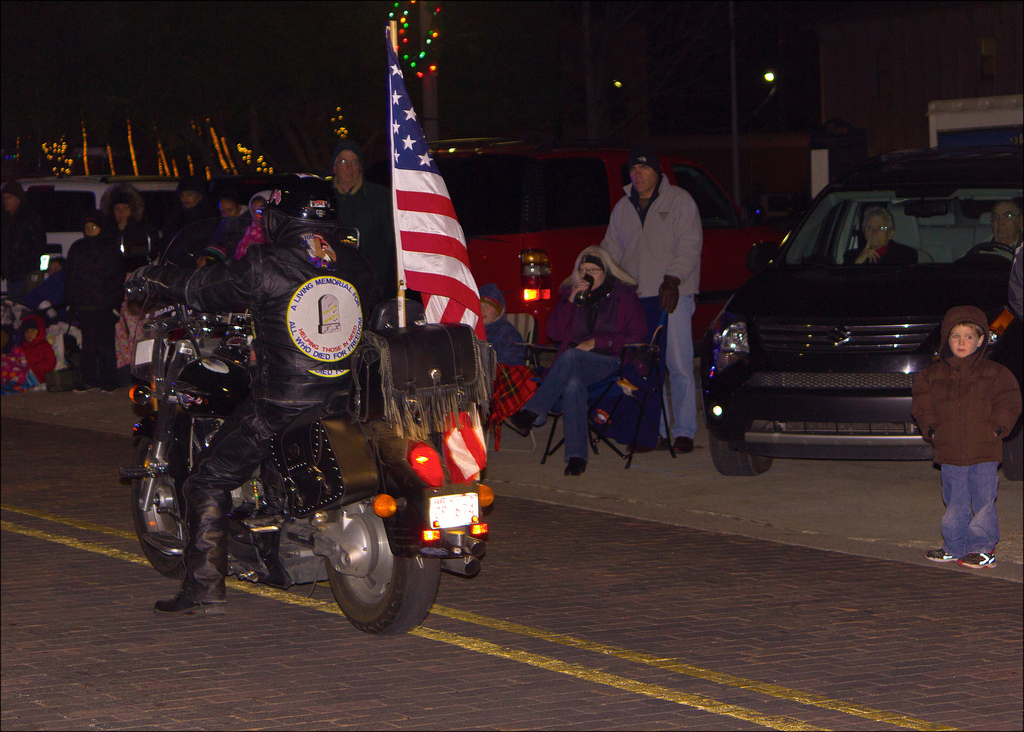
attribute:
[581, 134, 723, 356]
person — outdoors, here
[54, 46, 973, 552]
outdoors — here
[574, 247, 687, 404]
person — sitting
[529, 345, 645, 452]
jeans — blue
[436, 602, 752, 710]
lines — yellow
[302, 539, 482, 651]
tire — rubber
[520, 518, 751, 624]
street — black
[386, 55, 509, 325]
flag — american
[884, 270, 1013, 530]
boy — wearing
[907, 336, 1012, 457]
jacket — brown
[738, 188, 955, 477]
car — black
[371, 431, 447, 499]
light — red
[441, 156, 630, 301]
suv — red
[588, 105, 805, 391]
sweater — grey